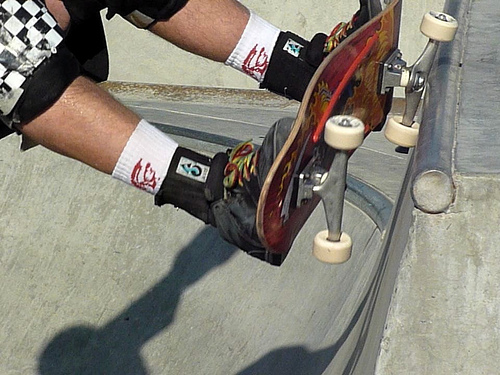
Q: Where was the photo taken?
A: It was taken at the pavement.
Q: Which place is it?
A: It is a pavement.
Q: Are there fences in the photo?
A: No, there are no fences.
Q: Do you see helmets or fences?
A: No, there are no fences or helmets.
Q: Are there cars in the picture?
A: No, there are no cars.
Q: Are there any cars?
A: No, there are no cars.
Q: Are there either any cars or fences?
A: No, there are no cars or fences.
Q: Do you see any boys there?
A: No, there are no boys.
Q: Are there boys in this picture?
A: No, there are no boys.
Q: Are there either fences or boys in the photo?
A: No, there are no boys or fences.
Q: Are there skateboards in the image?
A: Yes, there is a skateboard.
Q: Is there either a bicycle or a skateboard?
A: Yes, there is a skateboard.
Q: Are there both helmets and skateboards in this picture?
A: No, there is a skateboard but no helmets.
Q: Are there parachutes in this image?
A: No, there are no parachutes.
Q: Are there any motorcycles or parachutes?
A: No, there are no parachutes or motorcycles.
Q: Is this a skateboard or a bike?
A: This is a skateboard.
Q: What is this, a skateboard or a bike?
A: This is a skateboard.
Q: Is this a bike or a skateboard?
A: This is a skateboard.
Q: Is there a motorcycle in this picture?
A: No, there are no motorcycles.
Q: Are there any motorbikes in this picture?
A: No, there are no motorbikes.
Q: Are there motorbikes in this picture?
A: No, there are no motorbikes.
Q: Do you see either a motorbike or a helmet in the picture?
A: No, there are no motorcycles or helmets.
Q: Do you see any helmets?
A: No, there are no helmets.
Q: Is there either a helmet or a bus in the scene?
A: No, there are no helmets or buses.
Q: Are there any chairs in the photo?
A: No, there are no chairs.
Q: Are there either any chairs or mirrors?
A: No, there are no chairs or mirrors.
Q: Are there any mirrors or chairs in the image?
A: No, there are no chairs or mirrors.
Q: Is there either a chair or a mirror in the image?
A: No, there are no chairs or mirrors.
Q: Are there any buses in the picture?
A: No, there are no buses.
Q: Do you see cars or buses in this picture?
A: No, there are no buses or cars.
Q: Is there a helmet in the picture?
A: No, there are no helmets.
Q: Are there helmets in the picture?
A: No, there are no helmets.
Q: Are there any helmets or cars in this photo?
A: No, there are no helmets or cars.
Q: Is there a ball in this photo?
A: No, there are no balls.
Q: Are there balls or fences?
A: No, there are no balls or fences.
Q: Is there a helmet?
A: No, there are no helmets.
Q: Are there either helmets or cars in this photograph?
A: No, there are no helmets or cars.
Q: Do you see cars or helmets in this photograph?
A: No, there are no helmets or cars.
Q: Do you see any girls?
A: No, there are no girls.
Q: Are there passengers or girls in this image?
A: No, there are no girls or passengers.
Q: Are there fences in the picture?
A: No, there are no fences.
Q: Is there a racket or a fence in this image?
A: No, there are no fences or rackets.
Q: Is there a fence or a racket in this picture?
A: No, there are no fences or rackets.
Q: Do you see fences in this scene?
A: No, there are no fences.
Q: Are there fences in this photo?
A: No, there are no fences.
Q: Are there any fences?
A: No, there are no fences.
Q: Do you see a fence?
A: No, there are no fences.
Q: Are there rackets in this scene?
A: No, there are no rackets.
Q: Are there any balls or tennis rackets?
A: No, there are no tennis rackets or balls.